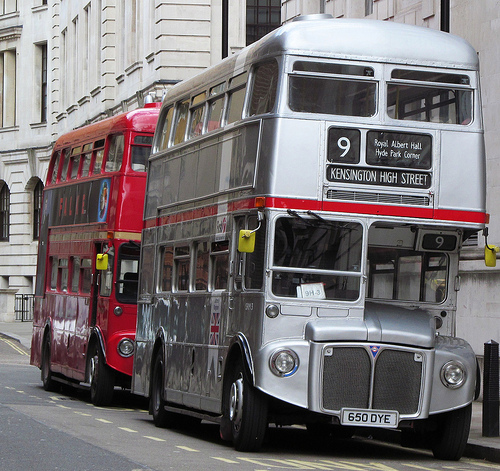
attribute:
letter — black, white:
[383, 413, 397, 434]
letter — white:
[419, 170, 442, 234]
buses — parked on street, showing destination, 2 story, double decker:
[46, 27, 476, 420]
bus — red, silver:
[49, 124, 166, 391]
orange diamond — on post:
[86, 187, 121, 233]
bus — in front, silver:
[149, 90, 485, 442]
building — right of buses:
[39, 16, 210, 75]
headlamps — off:
[279, 338, 463, 392]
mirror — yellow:
[92, 245, 124, 288]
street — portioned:
[16, 415, 84, 465]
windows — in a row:
[23, 30, 143, 95]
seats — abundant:
[298, 84, 373, 110]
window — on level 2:
[386, 65, 465, 120]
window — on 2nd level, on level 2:
[91, 139, 141, 171]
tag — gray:
[333, 398, 398, 437]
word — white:
[373, 139, 423, 160]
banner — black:
[336, 133, 361, 163]